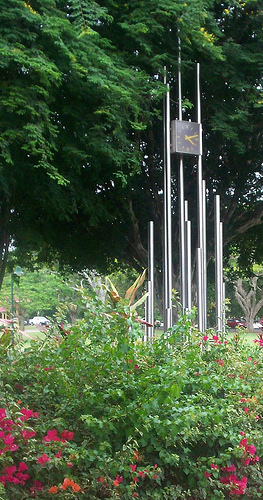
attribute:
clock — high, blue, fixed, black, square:
[145, 118, 229, 157]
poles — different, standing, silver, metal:
[133, 82, 253, 309]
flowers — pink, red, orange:
[1, 405, 76, 488]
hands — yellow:
[175, 133, 201, 155]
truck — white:
[15, 304, 62, 343]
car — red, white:
[217, 314, 249, 336]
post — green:
[0, 263, 51, 311]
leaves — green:
[30, 40, 124, 182]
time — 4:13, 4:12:
[160, 127, 224, 171]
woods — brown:
[126, 174, 261, 265]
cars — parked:
[19, 303, 259, 333]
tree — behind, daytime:
[22, 31, 261, 372]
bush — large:
[76, 321, 233, 458]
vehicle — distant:
[19, 308, 56, 330]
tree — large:
[19, 31, 170, 226]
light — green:
[7, 267, 33, 325]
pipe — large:
[128, 223, 194, 346]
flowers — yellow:
[177, 17, 257, 64]